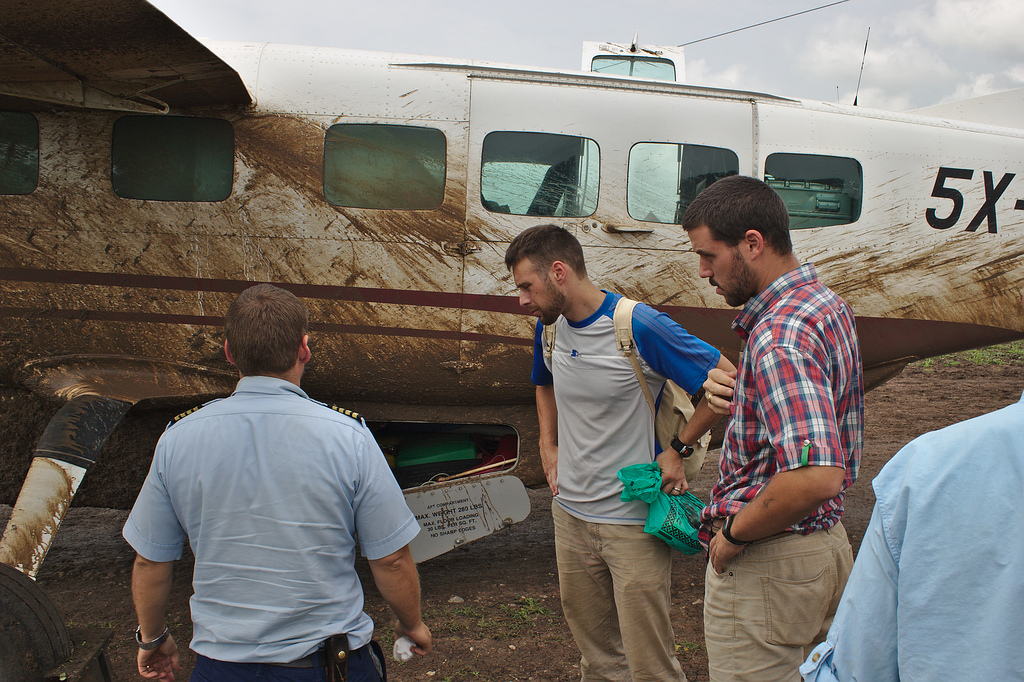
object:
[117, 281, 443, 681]
man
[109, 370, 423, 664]
uniform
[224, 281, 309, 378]
hair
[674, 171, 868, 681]
man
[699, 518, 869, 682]
pants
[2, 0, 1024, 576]
aircraft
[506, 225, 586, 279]
hair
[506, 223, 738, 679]
man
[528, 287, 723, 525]
shirt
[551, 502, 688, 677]
pants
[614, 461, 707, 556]
bag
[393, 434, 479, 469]
luggages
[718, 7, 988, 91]
cloud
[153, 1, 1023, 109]
sky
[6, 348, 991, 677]
surface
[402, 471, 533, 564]
door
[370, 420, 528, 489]
compartment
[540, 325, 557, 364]
strap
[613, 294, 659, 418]
strap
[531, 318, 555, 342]
shoulder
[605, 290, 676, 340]
shoulder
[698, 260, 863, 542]
shirt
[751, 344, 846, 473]
sleeves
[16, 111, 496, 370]
mud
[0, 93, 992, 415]
side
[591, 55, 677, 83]
glass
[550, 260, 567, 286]
ear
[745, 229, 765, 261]
ear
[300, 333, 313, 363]
ear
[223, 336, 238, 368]
ear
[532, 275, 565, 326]
beard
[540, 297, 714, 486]
backpack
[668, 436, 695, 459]
watch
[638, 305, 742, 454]
arms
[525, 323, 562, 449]
arms